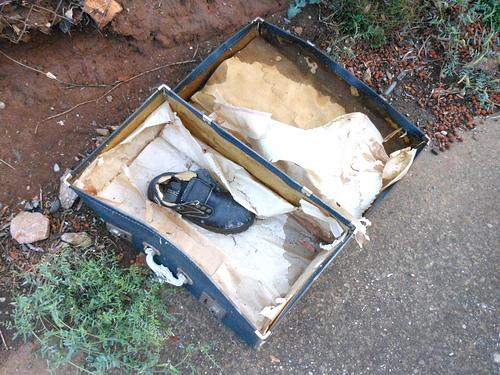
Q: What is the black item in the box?
A: A shoe.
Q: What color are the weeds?
A: Green.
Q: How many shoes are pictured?
A: One.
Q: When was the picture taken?
A: Daytime.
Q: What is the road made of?
A: Asphalt.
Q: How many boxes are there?
A: One.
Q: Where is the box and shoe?
A: On the side of the road.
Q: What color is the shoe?
A: Black.